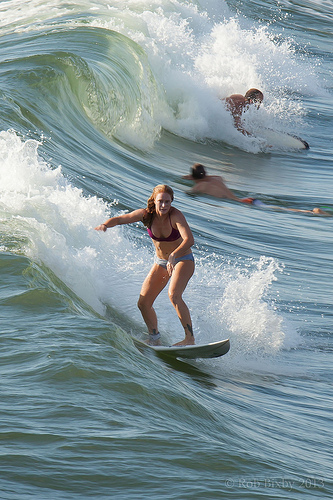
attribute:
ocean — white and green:
[26, 9, 283, 146]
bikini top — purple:
[146, 215, 181, 242]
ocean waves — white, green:
[9, 25, 169, 132]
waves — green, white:
[50, 22, 156, 152]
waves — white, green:
[28, 44, 140, 133]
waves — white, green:
[16, 168, 261, 354]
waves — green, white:
[43, 10, 257, 142]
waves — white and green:
[49, 28, 319, 272]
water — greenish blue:
[51, 394, 316, 479]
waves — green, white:
[33, 179, 86, 299]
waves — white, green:
[225, 255, 311, 344]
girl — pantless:
[93, 183, 195, 346]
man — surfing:
[219, 88, 271, 148]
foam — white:
[37, 179, 139, 323]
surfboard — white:
[109, 301, 243, 367]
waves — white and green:
[71, 233, 330, 431]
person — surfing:
[93, 182, 197, 346]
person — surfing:
[181, 162, 323, 215]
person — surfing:
[216, 88, 274, 148]